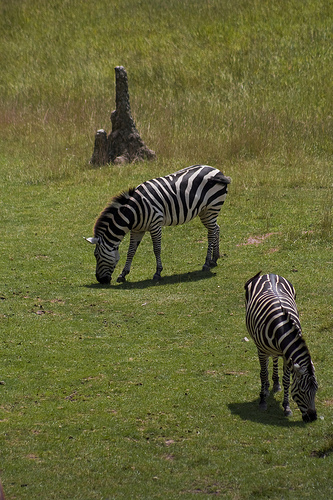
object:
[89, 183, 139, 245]
mohawk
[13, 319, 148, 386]
grass field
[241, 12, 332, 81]
grass field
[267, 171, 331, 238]
grass field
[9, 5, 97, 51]
grass field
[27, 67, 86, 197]
grass field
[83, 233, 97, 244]
zebra ear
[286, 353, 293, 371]
zebra ear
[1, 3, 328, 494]
land scape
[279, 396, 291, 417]
zebra hooves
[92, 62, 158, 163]
rock structure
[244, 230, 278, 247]
dirt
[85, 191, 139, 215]
mane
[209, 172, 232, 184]
tail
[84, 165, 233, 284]
zebra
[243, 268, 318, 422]
zebra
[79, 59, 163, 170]
ant hill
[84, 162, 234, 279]
animal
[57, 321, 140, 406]
grass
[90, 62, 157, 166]
structure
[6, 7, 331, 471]
savannah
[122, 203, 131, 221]
black stripes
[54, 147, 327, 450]
grass